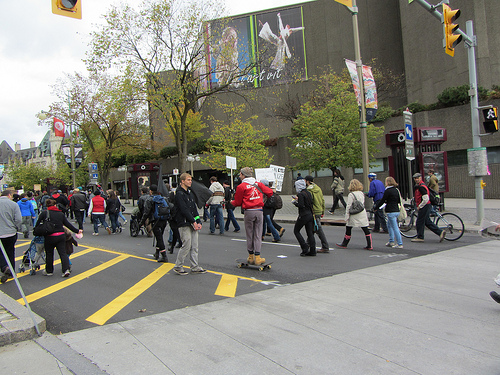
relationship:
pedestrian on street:
[425, 167, 440, 203] [1, 212, 498, 373]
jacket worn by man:
[230, 178, 275, 210] [228, 164, 273, 266]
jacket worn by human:
[0, 195, 27, 236] [0, 185, 29, 282]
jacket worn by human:
[141, 197, 176, 231] [140, 182, 178, 265]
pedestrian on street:
[371, 172, 407, 250] [26, 189, 486, 373]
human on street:
[205, 176, 225, 235] [21, 228, 477, 325]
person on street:
[338, 178, 373, 250] [1, 212, 498, 373]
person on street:
[89, 189, 106, 255] [96, 237, 481, 355]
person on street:
[172, 164, 202, 281] [96, 237, 481, 355]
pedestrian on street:
[291, 179, 316, 256] [96, 237, 481, 355]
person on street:
[35, 193, 80, 296] [96, 237, 481, 355]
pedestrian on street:
[373, 176, 408, 248] [96, 237, 481, 355]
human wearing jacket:
[199, 169, 232, 231] [241, 177, 262, 211]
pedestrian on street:
[287, 179, 321, 259] [1, 212, 498, 373]